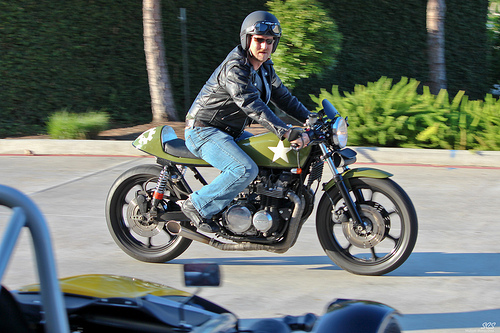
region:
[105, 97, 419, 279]
green motorcycle with white star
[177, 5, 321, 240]
man wearing leather jacket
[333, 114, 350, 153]
white headlight on front of bike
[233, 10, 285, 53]
man wearing black helmet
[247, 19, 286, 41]
goggles on front of helmet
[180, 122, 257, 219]
man wearing blue jeans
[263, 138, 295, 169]
white star on side of bike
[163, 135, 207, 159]
black seat on bike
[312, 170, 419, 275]
front wheel of bike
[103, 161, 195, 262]
rear wheel of bike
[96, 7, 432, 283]
The man is riding a motorcycle.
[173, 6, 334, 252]
The man is wearing a helmet.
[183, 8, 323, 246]
The man is wearing sunglasses.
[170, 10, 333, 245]
The man is wearing a jacket.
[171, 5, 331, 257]
The man is wearing blue jeans.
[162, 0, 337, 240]
The man's jacket is black.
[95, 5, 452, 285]
The motorcycle is green and white.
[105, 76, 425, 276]
The motorcycle has a white star on the gas tank.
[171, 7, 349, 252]
The man's jacket is leather.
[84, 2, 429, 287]
The motorcycle has two wheels.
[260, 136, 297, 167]
star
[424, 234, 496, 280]
shadow on the ground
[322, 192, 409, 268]
front tire of the motorcycle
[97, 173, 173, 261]
back tire of the motorcycle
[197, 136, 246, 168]
the man is wearing blue jeans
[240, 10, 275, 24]
a helmet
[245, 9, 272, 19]
the helmet is grey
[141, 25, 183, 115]
a tree trunk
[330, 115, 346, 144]
a headlight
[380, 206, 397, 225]
Small metal spoke in a wheel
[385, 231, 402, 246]
Small metal spoke in a wheel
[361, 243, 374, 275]
Small metal spoke in a wheel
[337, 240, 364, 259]
Small metal spoke in a wheel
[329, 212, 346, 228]
Small metal spoke in a wheel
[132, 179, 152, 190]
Small metal spoke in a wheel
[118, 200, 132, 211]
Small metal spoke in a wheel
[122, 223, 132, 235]
Small metal spoke in a wheel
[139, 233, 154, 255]
Small metal spoke in a wheel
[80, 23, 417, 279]
Man on a motorcycle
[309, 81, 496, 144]
green leaves of bush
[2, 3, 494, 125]
surface of trimmed hedge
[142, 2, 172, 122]
bark of tree trunk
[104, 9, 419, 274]
man riding on motorbike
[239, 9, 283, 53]
helmet and goggles on head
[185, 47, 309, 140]
leather coat on man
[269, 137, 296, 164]
white star on green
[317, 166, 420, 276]
green fender over wheel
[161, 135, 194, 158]
black leather bike seat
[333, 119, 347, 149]
headlight on front of bike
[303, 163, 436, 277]
front tire of the bike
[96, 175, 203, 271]
back tire of the bike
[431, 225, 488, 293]
shadow on the ground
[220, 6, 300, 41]
helmet on the man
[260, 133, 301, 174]
logo on the bike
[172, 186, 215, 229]
foot of the man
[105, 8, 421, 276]
a man riding a motorcycle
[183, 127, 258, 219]
a pair of blue jeans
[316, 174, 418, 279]
a motorcycle front tire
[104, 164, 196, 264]
a motorcycle rear tire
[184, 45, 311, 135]
a black leather jacket